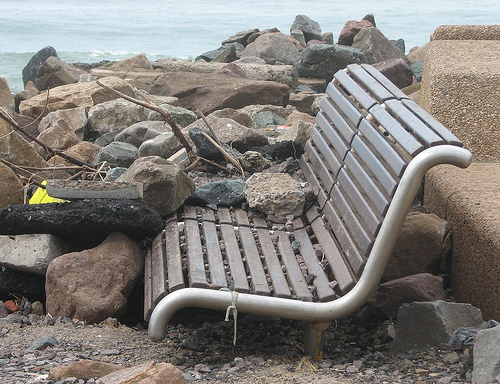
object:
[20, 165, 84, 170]
twig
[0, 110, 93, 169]
twig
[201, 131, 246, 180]
twig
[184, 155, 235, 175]
twig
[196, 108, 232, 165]
twig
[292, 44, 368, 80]
boulder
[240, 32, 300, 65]
boulder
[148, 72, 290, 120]
boulder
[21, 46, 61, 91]
boulder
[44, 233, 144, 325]
boulder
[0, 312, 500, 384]
debris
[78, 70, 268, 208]
rocks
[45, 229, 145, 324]
rock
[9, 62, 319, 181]
pile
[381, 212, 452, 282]
rock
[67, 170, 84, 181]
twigs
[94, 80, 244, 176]
sticks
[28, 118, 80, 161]
rock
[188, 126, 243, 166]
rock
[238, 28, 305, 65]
rock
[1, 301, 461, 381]
ground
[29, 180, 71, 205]
debris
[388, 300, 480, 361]
rocks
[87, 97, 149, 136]
boulders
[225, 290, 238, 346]
rope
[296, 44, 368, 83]
boulder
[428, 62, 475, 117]
steps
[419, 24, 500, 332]
stone wall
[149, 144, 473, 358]
side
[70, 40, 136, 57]
waves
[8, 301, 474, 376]
gravel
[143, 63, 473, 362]
park bench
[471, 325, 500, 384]
rock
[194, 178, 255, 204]
rock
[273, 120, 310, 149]
rock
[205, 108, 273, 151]
rock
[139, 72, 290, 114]
rock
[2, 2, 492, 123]
shoreline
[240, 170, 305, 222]
rock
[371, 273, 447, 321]
rock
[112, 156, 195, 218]
rock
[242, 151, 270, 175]
rock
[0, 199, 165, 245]
asphalt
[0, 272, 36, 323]
object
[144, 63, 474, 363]
bench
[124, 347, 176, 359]
dirt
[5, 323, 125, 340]
dirt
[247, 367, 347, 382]
dirt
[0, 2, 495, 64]
sea water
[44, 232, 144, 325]
large rocks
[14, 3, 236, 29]
ocean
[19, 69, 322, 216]
several rocks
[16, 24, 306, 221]
rocks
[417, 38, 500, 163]
block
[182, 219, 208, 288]
bar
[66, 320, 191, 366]
dirt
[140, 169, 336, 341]
seat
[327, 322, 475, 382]
rocks